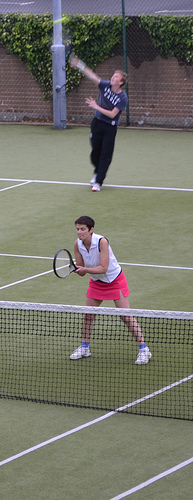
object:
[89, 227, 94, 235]
ear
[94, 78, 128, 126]
t-shirt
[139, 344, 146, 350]
sock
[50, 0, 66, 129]
pole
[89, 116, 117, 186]
black pants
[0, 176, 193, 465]
lines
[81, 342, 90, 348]
sock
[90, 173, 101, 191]
white shoe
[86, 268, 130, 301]
skirt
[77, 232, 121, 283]
top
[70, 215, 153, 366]
lady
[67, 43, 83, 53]
floor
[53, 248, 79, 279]
racket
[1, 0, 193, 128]
wall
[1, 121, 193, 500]
green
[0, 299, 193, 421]
mesh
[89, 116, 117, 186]
pants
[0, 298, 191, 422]
net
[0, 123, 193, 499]
court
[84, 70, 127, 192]
man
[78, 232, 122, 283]
shirt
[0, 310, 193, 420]
net